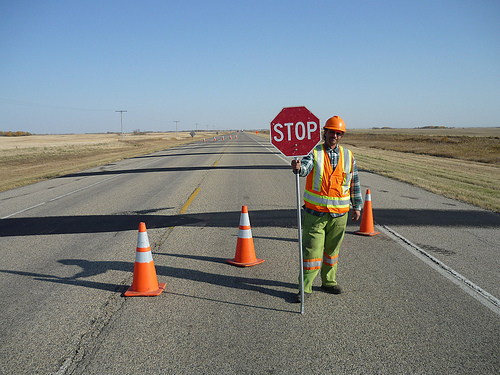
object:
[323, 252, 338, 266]
stripe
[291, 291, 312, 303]
sneaker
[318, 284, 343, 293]
sneaker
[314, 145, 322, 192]
patch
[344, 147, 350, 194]
patch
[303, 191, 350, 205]
patch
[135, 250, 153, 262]
stripe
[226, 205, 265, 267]
cone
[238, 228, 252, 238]
stripe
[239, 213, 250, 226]
stripe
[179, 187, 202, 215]
line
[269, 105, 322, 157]
sign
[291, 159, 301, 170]
hand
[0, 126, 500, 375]
ground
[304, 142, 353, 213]
vest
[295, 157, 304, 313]
pole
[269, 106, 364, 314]
man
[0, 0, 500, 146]
background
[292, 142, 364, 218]
shirt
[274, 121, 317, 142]
letter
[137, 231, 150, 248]
stripe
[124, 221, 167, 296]
cone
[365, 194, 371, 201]
white stripe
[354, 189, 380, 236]
cone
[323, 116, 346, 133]
hard hat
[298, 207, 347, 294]
green pants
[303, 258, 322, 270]
orange stripes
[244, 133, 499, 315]
white line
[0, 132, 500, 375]
road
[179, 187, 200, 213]
yellow lines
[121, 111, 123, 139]
pole